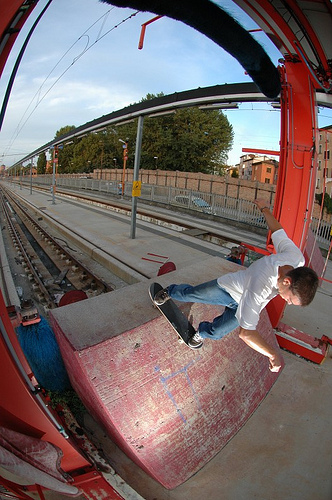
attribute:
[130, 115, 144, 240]
post — metal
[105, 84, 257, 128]
rail — metal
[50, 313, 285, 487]
ramp — red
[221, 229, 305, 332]
shirt — worn, white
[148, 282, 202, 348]
skateboard — black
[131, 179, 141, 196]
sign — yellow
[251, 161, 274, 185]
building — red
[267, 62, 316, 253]
post — red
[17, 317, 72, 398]
brush — blue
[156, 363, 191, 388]
mark — blue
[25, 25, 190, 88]
sky — blue